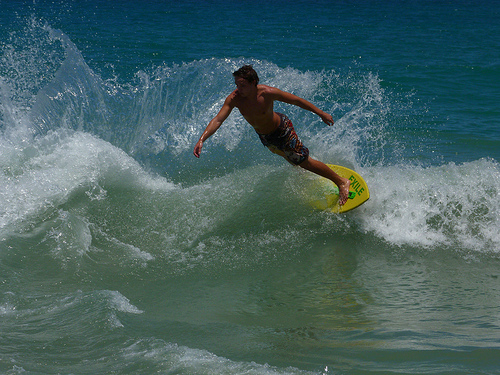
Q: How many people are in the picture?
A: One.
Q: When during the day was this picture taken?
A: Daytime.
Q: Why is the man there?
A: To surf.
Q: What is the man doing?
A: Surfing.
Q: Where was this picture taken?
A: Beach.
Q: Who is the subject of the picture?
A: Surfer.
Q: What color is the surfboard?
A: Yellow.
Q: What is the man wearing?
A: Board shorts.